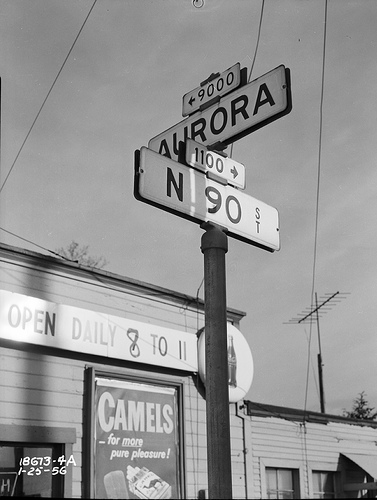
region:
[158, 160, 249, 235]
street sign says N 90 ST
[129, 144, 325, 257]
street sign says N 90 ST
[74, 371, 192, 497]
an ad on the wall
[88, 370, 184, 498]
cigarette advertising poster on a building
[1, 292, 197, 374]
store hours sign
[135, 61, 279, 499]
pole with street signs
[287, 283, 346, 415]
antenna on the roof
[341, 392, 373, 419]
top of tree near the antenna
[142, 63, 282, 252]
corner of North 90th and Aurora street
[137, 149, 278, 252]
white North 90th street sign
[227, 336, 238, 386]
Coca Cola bottle on the sign on the building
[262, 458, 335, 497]
double windows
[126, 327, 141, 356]
number on building changed from seven to eight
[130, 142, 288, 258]
a street sign on a pole.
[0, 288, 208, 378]
A sign mounted on a wall.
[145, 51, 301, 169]
an aurora street sign.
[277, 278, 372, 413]
an antennae on a roof top.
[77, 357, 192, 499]
a sign on a building.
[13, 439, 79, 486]
A serial number on a photo.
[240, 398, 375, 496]
a single story building.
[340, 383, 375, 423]
a tree with pine needles.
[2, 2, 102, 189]
a power line above a building.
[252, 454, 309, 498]
a window on a building.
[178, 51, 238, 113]
sign that says "9000" and points to the left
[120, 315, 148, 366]
number seven that is drawn over with a number eight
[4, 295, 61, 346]
sign that says "open"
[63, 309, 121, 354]
sign that says "DAILY"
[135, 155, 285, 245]
sign for North 90 St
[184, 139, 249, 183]
sign that says "1100" and points to the right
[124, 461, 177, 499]
advertisement showing a pack of Camels cigarettes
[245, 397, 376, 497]
building with aluminum siding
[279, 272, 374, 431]
old fashioned antennae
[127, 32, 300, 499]
sign poll with street signs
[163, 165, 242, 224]
black letters on white sign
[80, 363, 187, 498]
poster on a building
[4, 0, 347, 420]
power lines above building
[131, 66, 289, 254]
white signs above a pole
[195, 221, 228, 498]
pole under two white signs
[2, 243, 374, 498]
building behind black pole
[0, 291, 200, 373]
white sign on building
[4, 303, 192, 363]
black letters on white sign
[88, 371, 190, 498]
poster on building is gray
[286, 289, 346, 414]
black antenna on building